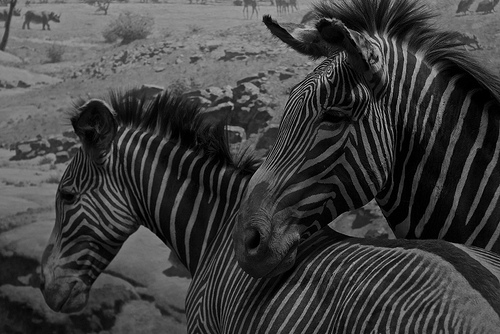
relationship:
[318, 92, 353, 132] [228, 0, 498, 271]
eye on zebra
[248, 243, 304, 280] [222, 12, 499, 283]
mouth of a zebra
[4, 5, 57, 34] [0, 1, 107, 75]
animal in corner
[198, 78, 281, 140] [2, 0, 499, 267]
rocks are on ground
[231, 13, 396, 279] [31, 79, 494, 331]
head on top of zebra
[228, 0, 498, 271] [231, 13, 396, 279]
zebra has head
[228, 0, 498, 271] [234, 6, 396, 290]
zebra has head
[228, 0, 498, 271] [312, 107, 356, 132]
zebra has eye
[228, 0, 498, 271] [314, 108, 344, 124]
zebra has eye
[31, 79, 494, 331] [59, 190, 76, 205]
zebra has eye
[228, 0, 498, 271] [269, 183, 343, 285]
zebra has jaw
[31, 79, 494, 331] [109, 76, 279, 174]
zebra has mane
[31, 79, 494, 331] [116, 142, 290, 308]
zebra has neck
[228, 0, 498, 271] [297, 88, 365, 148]
zebra has eye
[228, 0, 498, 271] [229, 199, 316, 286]
zebra has nose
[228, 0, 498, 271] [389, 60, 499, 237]
zebra has neck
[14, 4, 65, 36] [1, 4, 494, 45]
animal in distance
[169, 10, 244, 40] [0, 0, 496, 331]
background in photo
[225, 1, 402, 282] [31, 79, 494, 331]
head over zebra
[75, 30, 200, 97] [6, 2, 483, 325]
rocks are on ground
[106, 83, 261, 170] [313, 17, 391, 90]
hairs behind ear zebra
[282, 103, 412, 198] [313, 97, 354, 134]
stripes to side of eye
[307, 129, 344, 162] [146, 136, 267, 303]
stripe between stripes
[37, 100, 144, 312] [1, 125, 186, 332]
animal's head against flat rocks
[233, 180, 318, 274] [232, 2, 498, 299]
nose of zebra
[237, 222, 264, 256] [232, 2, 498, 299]
nostril of zebra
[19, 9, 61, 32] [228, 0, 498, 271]
animal behind zebra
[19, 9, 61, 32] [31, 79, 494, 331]
animal behind zebra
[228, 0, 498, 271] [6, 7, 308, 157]
zebra in field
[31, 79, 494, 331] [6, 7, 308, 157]
zebra in field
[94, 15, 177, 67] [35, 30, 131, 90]
bush on ground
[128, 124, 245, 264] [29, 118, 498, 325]
neck of zebra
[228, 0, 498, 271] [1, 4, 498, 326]
zebra in field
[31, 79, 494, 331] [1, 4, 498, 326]
zebra in field